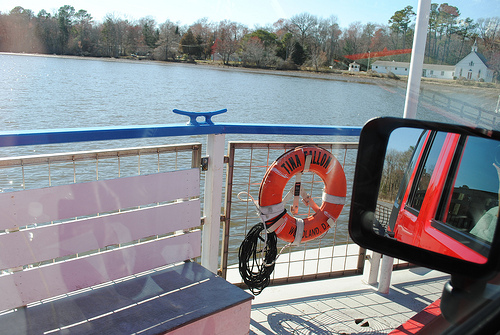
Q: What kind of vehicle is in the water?
A: Red suv.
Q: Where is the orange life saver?
A: Attached to gate fence.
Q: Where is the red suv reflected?
A: Rear view mirror.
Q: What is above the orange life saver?
A: Blue bar.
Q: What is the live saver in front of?
A: Body of water.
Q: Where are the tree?
A: Bordering the body of water.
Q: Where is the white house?
A: To the right of the line of foliage.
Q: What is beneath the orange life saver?
A: Black cord.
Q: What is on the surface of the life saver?
A: Black writing.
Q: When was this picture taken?
A: Daytime.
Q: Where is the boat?
A: The river.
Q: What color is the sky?
A: Blue.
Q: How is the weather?
A: Sunny.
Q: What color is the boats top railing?
A: Blue.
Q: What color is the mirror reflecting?
A: Red.